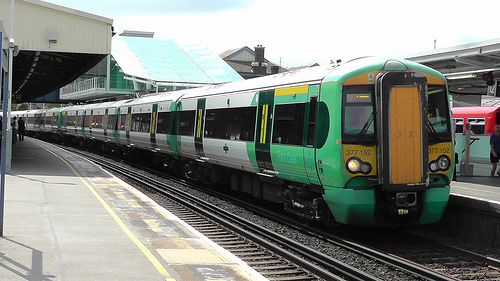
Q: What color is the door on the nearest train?
A: Yellow.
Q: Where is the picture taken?
A: Train station.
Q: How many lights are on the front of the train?
A: Four.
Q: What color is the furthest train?
A: Red.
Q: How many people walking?
A: One.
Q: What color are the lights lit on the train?
A: Yellow.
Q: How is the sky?
A: Bright.